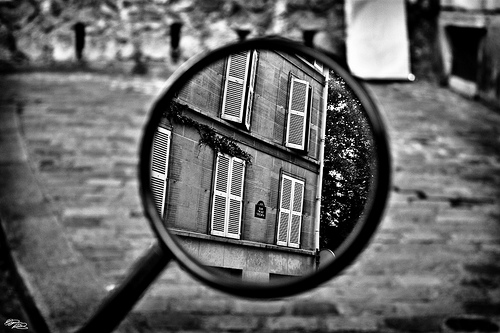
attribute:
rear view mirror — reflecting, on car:
[138, 37, 392, 300]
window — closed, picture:
[210, 152, 246, 238]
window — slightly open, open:
[283, 77, 318, 160]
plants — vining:
[322, 69, 375, 251]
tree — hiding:
[323, 70, 376, 250]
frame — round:
[137, 37, 391, 299]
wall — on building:
[158, 48, 330, 281]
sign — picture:
[254, 199, 266, 218]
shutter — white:
[210, 151, 232, 237]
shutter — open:
[285, 78, 309, 150]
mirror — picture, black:
[138, 39, 390, 301]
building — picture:
[148, 46, 329, 277]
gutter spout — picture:
[315, 64, 329, 251]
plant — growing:
[168, 110, 252, 161]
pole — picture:
[312, 71, 329, 249]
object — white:
[343, 1, 417, 81]